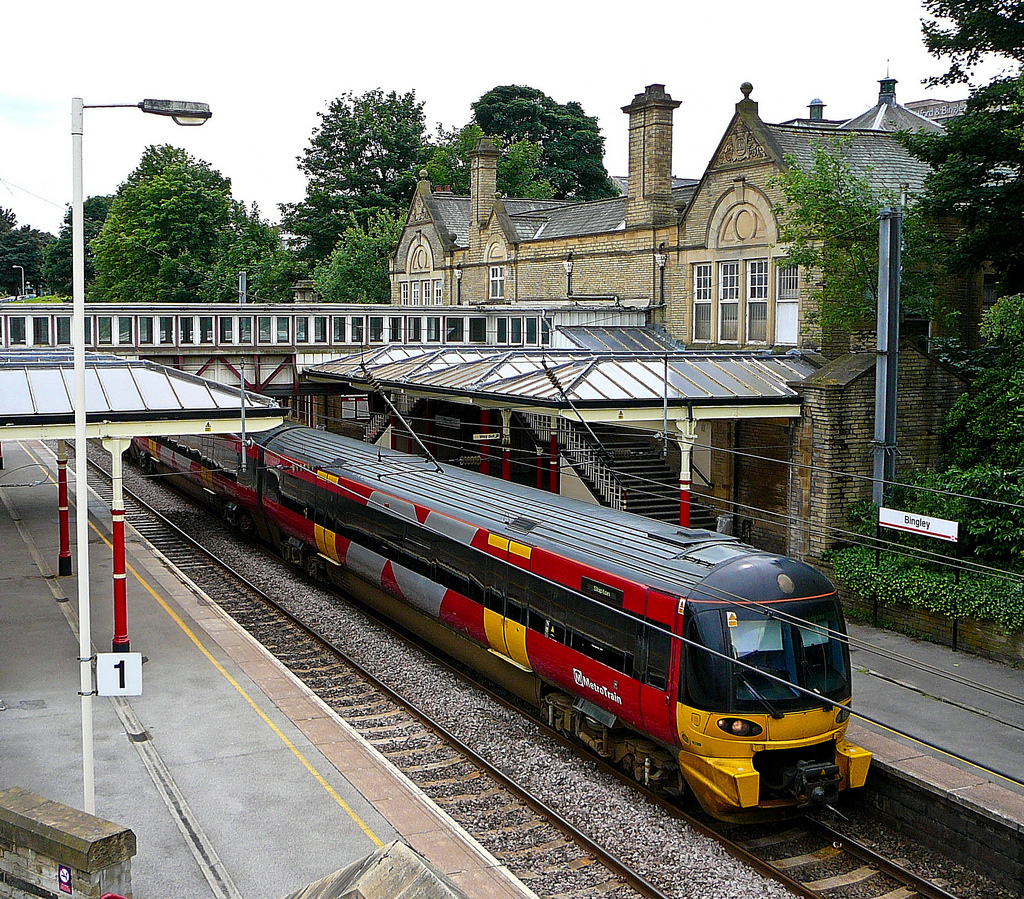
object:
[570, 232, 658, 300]
wall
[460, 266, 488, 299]
wall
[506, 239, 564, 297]
wall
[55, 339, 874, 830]
train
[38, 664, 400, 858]
platform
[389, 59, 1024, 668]
building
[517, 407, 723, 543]
stairs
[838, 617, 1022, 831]
platform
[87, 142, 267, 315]
trees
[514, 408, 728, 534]
cases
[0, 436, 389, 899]
crosswalk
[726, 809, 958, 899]
tracks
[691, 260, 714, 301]
windows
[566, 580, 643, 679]
window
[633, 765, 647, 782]
wheels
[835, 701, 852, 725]
headlight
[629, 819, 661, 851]
gravel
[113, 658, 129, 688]
1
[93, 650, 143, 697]
sign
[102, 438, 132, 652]
poles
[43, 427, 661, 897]
tracks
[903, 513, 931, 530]
writing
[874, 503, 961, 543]
sign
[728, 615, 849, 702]
windows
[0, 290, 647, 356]
bridge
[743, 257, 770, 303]
windows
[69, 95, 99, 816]
post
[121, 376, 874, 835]
tracks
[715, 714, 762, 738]
headlight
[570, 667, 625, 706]
writing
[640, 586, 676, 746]
door